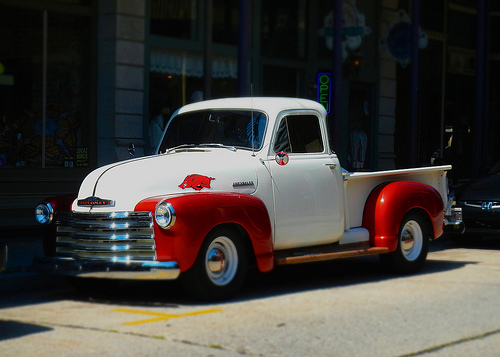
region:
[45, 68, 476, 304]
old red and white truck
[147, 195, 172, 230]
silver light on truck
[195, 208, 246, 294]
black and white tire on truck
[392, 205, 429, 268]
black and white tire on truck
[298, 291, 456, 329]
gray pavement in street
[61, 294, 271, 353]
gray pavement in street with yellow lines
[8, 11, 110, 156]
aqua window of shop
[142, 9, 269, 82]
aqua window of shop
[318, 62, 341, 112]
blue and green sign outside of shop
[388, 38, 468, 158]
door of shop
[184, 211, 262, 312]
tires are black and white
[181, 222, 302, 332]
tires are black and white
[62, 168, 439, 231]
The truck is mostly white.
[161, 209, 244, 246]
The fender is red.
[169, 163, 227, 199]
Red animal on the car.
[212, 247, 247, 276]
The rim is white.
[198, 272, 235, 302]
The wheel is black.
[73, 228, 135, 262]
The grill is silver.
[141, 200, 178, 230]
The light is silver.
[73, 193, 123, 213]
Make of the truck.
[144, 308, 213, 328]
Yellow line on the road.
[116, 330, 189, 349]
Grass growing in a crack on the road.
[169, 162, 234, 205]
red boar on vehicle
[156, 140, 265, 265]
red boar on vehicle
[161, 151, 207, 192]
red boar on vehicle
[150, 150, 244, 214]
red boar on vehicle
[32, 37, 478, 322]
old-fashioned truck parked in sun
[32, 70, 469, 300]
white vehicle with red highlights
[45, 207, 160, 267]
wide grill in front of car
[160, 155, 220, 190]
red pig-like animal on side of car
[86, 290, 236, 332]
yellow guidelines on street for parking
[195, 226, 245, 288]
silver and white hubcaps against black tires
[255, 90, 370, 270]
white door on driver's side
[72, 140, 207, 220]
metal stripe over middle of hood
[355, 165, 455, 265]
red and curved metal over rear wheel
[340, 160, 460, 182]
edge on side of open truck